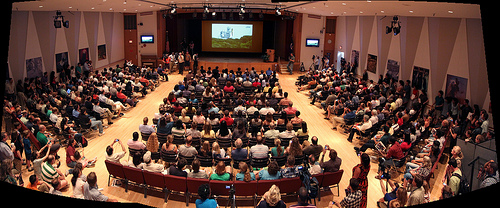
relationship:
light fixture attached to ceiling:
[272, 6, 284, 18] [9, 1, 478, 28]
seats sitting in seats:
[117, 162, 143, 190] [105, 160, 126, 190]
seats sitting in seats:
[141, 170, 167, 202] [105, 160, 126, 190]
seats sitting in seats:
[164, 174, 188, 202] [105, 160, 126, 190]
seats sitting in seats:
[186, 178, 210, 203] [105, 160, 126, 190]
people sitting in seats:
[105, 137, 126, 164] [105, 160, 126, 190]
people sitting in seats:
[121, 148, 140, 168] [105, 160, 126, 190]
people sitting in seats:
[144, 151, 167, 173] [105, 160, 126, 190]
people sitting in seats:
[167, 155, 188, 181] [105, 160, 126, 190]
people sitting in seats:
[187, 160, 207, 180] [105, 160, 126, 190]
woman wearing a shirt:
[209, 160, 233, 180] [210, 172, 230, 179]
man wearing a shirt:
[342, 180, 358, 206] [337, 190, 364, 205]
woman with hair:
[215, 121, 233, 145] [218, 120, 229, 135]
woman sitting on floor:
[64, 138, 81, 164] [110, 121, 130, 138]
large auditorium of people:
[2, 0, 482, 205] [6, 47, 482, 167]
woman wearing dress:
[352, 150, 372, 207] [349, 164, 371, 204]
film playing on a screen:
[202, 23, 260, 54] [213, 24, 255, 48]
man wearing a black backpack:
[446, 158, 464, 200] [450, 168, 471, 203]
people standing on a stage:
[168, 39, 197, 60] [162, 11, 295, 70]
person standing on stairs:
[287, 53, 295, 73] [281, 65, 295, 73]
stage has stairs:
[179, 48, 304, 67] [281, 65, 295, 73]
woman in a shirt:
[193, 172, 225, 200] [213, 173, 237, 181]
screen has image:
[197, 17, 266, 57] [207, 17, 257, 50]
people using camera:
[105, 137, 129, 164] [112, 138, 118, 146]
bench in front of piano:
[142, 61, 153, 64] [137, 52, 160, 65]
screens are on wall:
[126, 16, 387, 68] [123, 10, 332, 66]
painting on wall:
[349, 47, 359, 68] [333, 12, 494, 113]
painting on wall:
[381, 57, 401, 85] [333, 12, 494, 113]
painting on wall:
[363, 51, 377, 74] [333, 12, 494, 113]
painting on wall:
[408, 64, 431, 94] [333, 12, 494, 113]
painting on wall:
[441, 72, 469, 102] [333, 12, 494, 113]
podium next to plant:
[268, 48, 275, 62] [276, 50, 284, 58]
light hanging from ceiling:
[384, 15, 406, 35] [277, 0, 484, 20]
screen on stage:
[197, 17, 267, 56] [155, 4, 302, 76]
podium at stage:
[268, 48, 275, 62] [162, 11, 295, 70]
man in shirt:
[39, 153, 61, 191] [39, 161, 59, 186]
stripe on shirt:
[43, 162, 58, 177] [39, 161, 59, 186]